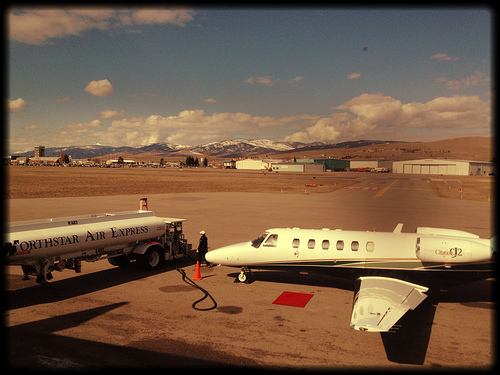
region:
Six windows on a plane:
[289, 233, 379, 259]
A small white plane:
[199, 216, 498, 341]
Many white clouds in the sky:
[6, 8, 492, 149]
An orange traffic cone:
[189, 255, 206, 283]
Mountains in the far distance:
[15, 134, 411, 161]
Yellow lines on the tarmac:
[346, 173, 401, 202]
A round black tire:
[136, 240, 169, 276]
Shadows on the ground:
[5, 245, 493, 367]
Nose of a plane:
[203, 231, 251, 271]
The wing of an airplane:
[347, 273, 431, 337]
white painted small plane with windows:
[206, 212, 494, 354]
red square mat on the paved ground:
[261, 285, 326, 319]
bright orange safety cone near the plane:
[189, 254, 205, 287]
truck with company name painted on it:
[6, 206, 191, 306]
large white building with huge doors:
[388, 148, 493, 190]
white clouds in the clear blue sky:
[86, 93, 241, 144]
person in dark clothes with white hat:
[193, 227, 212, 264]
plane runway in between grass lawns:
[326, 169, 451, 208]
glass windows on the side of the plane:
[294, 235, 386, 252]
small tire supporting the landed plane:
[235, 264, 248, 289]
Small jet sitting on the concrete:
[198, 220, 493, 337]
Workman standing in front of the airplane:
[193, 226, 211, 268]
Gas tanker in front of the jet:
[8, 214, 170, 290]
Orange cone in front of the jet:
[189, 258, 203, 282]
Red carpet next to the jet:
[267, 288, 314, 311]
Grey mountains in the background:
[10, 132, 427, 163]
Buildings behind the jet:
[9, 143, 496, 180]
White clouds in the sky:
[9, 6, 493, 155]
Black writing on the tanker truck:
[10, 222, 154, 254]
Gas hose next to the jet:
[170, 263, 222, 314]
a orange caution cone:
[191, 259, 204, 284]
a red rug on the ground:
[266, 273, 332, 325]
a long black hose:
[168, 263, 208, 333]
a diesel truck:
[5, 202, 197, 300]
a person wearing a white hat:
[194, 221, 208, 243]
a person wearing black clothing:
[194, 217, 208, 263]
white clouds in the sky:
[302, 81, 459, 136]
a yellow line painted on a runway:
[370, 172, 412, 207]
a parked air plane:
[209, 214, 475, 336]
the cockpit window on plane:
[252, 225, 277, 258]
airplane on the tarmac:
[198, 218, 498, 369]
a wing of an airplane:
[343, 274, 432, 334]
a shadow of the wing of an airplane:
[378, 288, 438, 368]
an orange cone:
[191, 258, 204, 279]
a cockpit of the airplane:
[250, 227, 280, 252]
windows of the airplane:
[288, 236, 376, 253]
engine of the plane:
[412, 233, 496, 266]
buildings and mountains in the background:
[5, 133, 495, 179]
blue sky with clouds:
[12, 10, 492, 140]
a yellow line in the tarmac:
[368, 175, 403, 202]